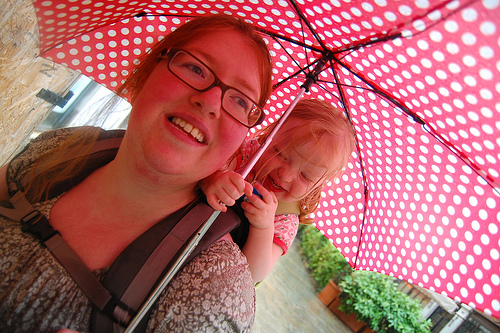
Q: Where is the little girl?
A: Behind the woman.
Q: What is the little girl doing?
A: She is laughing.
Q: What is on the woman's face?
A: Glasses.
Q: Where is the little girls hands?
A: On the umbrella.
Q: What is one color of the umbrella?
A: Red.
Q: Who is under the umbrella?
A: A woman and little girl.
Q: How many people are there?
A: Two.